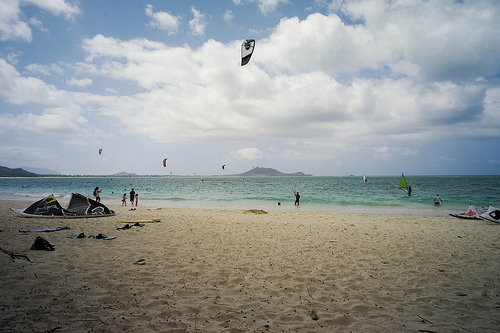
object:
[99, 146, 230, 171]
kites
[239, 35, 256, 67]
kite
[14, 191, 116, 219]
tent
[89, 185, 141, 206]
people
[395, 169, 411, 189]
sail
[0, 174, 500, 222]
water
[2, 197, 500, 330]
beach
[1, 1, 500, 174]
sky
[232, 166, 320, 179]
mountains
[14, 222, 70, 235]
surfboard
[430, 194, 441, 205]
person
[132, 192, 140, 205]
child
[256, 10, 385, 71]
cloud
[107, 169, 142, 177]
hill